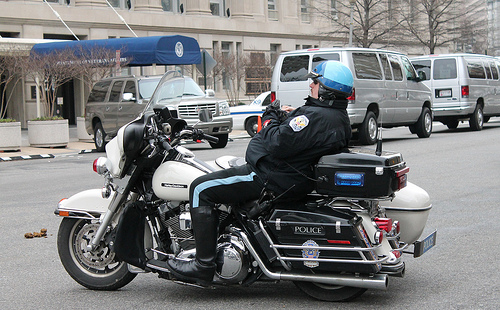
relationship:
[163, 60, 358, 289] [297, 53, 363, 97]
cop wearing helmet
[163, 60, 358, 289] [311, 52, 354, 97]
cop wearing helmet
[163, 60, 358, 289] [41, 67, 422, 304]
cop sitting on motorcycle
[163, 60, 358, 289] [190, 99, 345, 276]
cop wearing uniform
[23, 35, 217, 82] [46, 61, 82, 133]
awning over doorway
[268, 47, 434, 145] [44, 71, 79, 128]
cars parked by door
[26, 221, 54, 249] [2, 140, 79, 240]
trash laying on pavement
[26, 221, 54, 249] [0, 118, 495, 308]
trash laying on road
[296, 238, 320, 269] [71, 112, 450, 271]
sign on side of motorcycle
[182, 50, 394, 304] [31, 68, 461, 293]
cop sitting on motorcycle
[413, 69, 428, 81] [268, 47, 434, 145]
mirror on cars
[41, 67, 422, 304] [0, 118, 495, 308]
motorcycle on road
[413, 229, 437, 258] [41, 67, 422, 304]
license plate on motorcycle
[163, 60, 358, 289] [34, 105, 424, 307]
cop sitting on motorcycle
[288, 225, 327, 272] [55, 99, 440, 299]
sign on motorcycle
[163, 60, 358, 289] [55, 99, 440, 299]
cop on motorcycle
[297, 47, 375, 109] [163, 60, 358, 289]
helmet on cop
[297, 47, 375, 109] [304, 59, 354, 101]
helmet on head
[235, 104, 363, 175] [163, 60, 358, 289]
jacket on cop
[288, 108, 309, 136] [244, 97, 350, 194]
badge on jacket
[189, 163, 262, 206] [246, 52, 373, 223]
pants on man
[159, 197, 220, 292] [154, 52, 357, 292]
boot on man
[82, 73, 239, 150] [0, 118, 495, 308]
cars on road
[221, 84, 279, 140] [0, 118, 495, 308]
cars on road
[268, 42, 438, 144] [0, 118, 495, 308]
cars on road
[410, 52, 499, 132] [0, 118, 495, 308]
cars on road